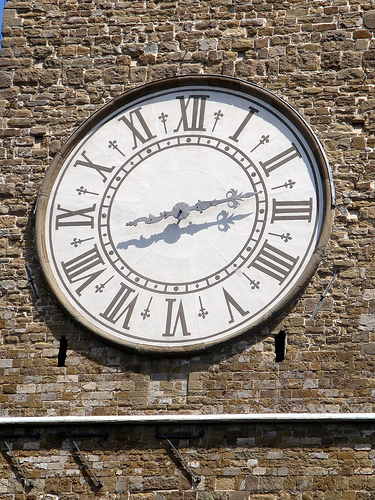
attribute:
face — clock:
[48, 83, 323, 347]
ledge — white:
[6, 408, 370, 427]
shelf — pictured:
[1, 405, 373, 423]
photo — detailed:
[2, 3, 372, 381]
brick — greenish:
[220, 14, 363, 100]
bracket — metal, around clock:
[303, 111, 339, 280]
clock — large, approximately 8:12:
[20, 70, 343, 360]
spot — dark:
[273, 329, 286, 363]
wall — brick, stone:
[1, 1, 373, 499]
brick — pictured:
[177, 446, 195, 452]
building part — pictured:
[7, 2, 373, 498]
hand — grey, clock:
[121, 188, 253, 229]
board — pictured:
[216, 411, 221, 423]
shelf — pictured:
[1, 405, 373, 453]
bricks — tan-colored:
[71, 336, 268, 402]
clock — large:
[42, 60, 327, 332]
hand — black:
[130, 183, 262, 223]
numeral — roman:
[260, 143, 303, 180]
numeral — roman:
[219, 98, 260, 148]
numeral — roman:
[170, 91, 209, 137]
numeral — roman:
[121, 109, 152, 147]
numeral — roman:
[73, 150, 114, 188]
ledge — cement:
[1, 411, 374, 427]